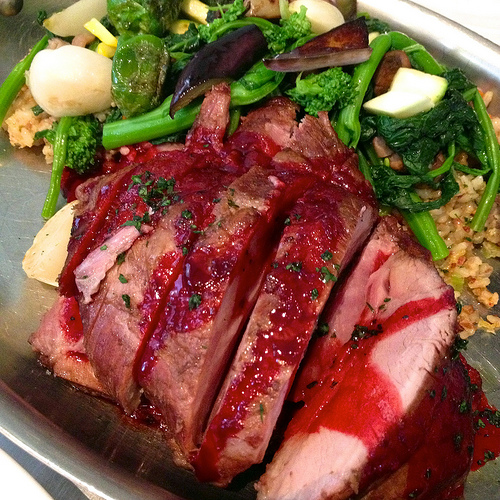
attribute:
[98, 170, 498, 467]
seasoning — green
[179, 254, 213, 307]
sauce — red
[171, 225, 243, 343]
sauce — red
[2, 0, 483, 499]
plate — silver